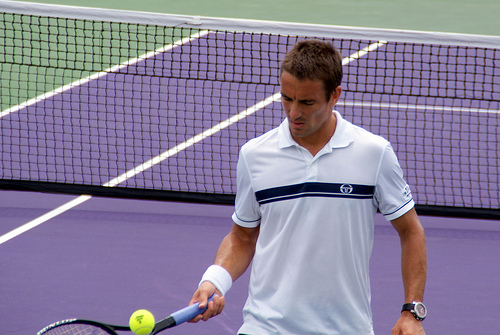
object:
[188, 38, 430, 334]
man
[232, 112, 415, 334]
shirt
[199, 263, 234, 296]
wristband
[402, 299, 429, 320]
watch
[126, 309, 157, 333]
tennis ball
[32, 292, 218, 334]
racket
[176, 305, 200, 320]
tape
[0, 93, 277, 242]
line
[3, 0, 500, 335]
court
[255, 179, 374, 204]
stripe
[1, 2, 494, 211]
net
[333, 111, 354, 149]
collar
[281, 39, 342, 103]
hair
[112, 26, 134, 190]
string